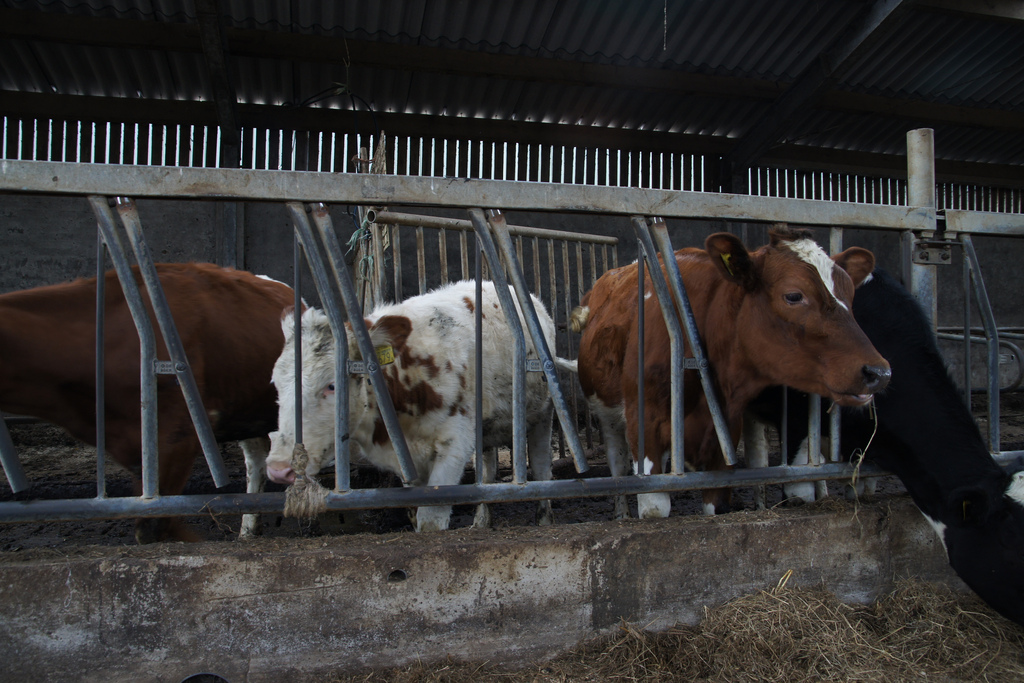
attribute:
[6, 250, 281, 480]
cow — standing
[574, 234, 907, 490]
cow — brown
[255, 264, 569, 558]
cow — brown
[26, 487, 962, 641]
barrier — concrete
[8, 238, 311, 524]
cow — brown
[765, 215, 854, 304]
spot — white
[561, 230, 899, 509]
cow — brown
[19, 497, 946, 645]
wall — concrete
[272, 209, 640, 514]
cow — white, brown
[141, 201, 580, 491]
cow — white, brown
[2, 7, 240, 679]
left — far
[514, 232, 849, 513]
cow — large, brown, white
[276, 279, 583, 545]
cow — white, brown, large